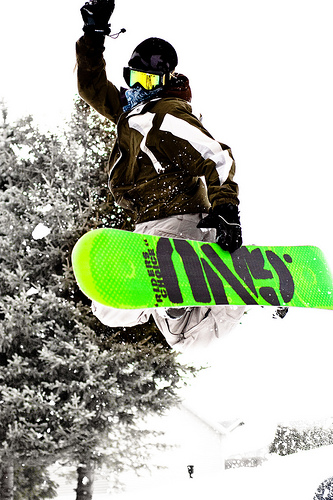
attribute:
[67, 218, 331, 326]
board — yellow, green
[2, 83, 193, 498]
leaves — covered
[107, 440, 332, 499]
snow — white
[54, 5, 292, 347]
man — snowskating, in air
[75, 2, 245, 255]
gloves — black, brown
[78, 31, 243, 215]
jacket — warm, brown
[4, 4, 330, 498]
background — white